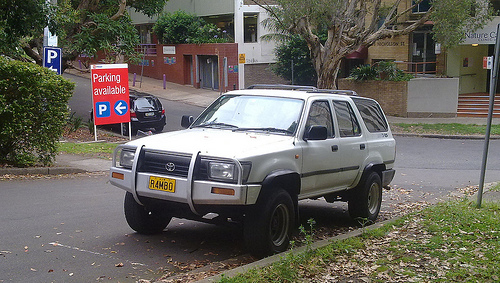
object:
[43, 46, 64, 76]
square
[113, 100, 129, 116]
arrow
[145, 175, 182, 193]
plate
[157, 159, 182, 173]
emblem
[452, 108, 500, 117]
steps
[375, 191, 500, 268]
grass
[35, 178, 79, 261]
road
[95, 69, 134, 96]
text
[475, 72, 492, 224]
pole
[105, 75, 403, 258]
suv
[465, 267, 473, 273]
leaves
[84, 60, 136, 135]
sign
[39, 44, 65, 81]
sign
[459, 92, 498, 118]
stair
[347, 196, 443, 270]
ground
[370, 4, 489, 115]
building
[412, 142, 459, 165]
street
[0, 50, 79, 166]
bush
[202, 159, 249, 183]
headlights